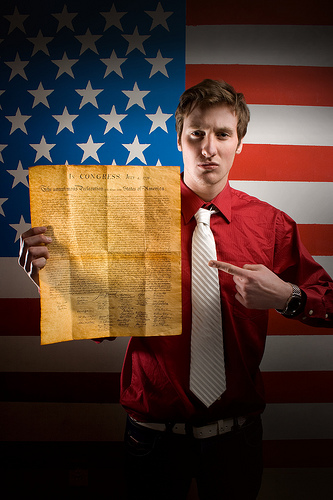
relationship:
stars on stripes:
[0, 0, 174, 246] [0, 0, 332, 499]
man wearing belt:
[17, 78, 332, 499] [125, 395, 265, 441]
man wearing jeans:
[17, 78, 332, 499] [120, 412, 262, 500]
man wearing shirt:
[17, 78, 332, 499] [92, 171, 332, 424]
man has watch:
[17, 78, 332, 499] [277, 282, 302, 320]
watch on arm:
[277, 282, 302, 320] [274, 211, 332, 331]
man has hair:
[17, 78, 332, 499] [174, 78, 250, 149]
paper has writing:
[28, 166, 183, 347] [38, 172, 174, 331]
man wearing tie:
[17, 78, 332, 499] [189, 208, 226, 406]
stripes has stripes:
[0, 0, 332, 499] [0, 0, 332, 499]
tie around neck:
[189, 208, 226, 406] [181, 170, 230, 205]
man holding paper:
[17, 78, 332, 499] [28, 166, 183, 347]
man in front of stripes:
[17, 78, 332, 499] [0, 0, 332, 499]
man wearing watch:
[17, 78, 332, 499] [277, 282, 302, 320]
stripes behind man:
[0, 0, 332, 499] [17, 78, 332, 499]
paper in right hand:
[28, 166, 183, 347] [18, 225, 50, 285]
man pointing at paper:
[17, 78, 332, 499] [28, 166, 183, 347]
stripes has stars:
[0, 0, 332, 499] [0, 0, 174, 246]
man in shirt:
[17, 78, 332, 499] [92, 171, 332, 424]